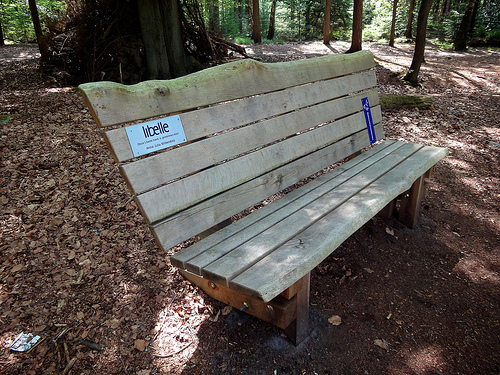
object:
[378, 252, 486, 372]
ground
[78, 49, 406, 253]
slat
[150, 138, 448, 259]
slat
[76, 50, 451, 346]
bench